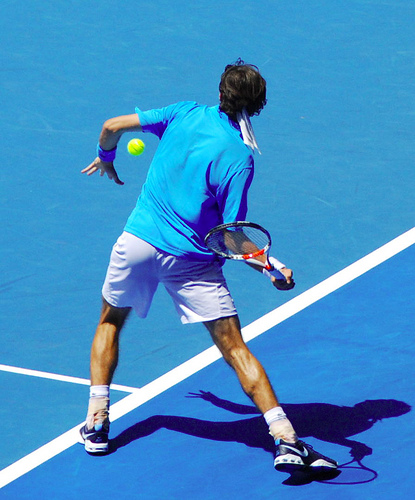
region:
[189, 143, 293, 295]
the racquet behind the mans back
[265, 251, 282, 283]
the white wristband on the tennis player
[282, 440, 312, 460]
the nike logo on the shoe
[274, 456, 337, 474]
the white sole of the shoe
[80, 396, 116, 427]
the brace on the ankle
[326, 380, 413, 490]
the players shadow on the tennis court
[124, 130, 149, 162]
the tennis ball in front of the player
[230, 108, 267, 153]
the white band in the hair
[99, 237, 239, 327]
the white shorts on the tennis player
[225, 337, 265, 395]
the calf muscle on the tennis player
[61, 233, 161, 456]
leg of a person playing tennis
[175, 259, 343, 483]
leg of a person playing tennis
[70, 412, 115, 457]
black and white tennis shoe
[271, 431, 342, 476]
black and white tennis shoe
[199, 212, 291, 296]
black and white tennis racket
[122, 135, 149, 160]
green tennis ball in the air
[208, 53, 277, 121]
head of a person playing tennis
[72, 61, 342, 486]
person wearing a blue shirt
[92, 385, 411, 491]
shadow of a person playing tennis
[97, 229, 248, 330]
pair of white tennis shorts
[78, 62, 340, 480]
a man playing tennis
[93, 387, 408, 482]
bright sun casting man's shadow on the court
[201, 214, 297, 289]
a multi-colored tennis racket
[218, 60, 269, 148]
the man is wearing a white headband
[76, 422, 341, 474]
the man wears Nike shoes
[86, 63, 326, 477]
the man is dressed completely in white and blue clothing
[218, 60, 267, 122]
the man has short brown hair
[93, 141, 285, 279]
the man is wearing wrist bands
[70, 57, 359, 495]
this is a person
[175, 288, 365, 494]
the leg of a person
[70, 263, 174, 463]
the leg of a person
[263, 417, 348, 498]
this is a sneaker shoe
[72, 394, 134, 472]
this is a sneaker shoe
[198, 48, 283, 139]
the man has black hair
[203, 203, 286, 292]
this is a racket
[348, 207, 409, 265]
this is a white line on a field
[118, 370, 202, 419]
this is a white line on a field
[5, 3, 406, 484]
man playing tennis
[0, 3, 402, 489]
a blue tennis court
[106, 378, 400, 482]
the man's shadow on the ground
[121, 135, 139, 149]
tennis ball in the air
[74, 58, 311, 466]
man about to hit the tennis ball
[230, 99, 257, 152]
the back of a headband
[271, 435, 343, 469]
black Nike shoes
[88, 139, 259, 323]
man wearing a blue shirt and white shorts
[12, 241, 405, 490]
white lines marking the boundaries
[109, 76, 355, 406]
a man playing tennis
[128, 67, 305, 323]
a man holding a tennis racket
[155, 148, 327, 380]
a man swinging a tennis racket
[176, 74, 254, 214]
a man wearing a shirt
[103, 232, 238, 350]
a man wearing short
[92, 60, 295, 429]
a man in a blue shirt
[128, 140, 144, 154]
a green tennis ball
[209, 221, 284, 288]
a tennis racket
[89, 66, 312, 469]
a man swinging a tennis racket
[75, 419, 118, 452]
the shoe of the man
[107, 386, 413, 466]
the shadow of the man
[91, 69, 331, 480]
a tennis player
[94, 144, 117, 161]
the sweat band on the mans wrist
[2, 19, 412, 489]
the blue tennis court